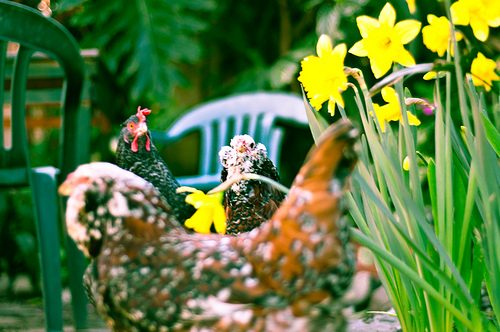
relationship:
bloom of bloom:
[447, 0, 499, 44] [447, 0, 498, 45]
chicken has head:
[108, 100, 194, 227] [123, 105, 148, 141]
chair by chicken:
[0, 0, 85, 330] [56, 97, 436, 332]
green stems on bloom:
[365, 128, 472, 329] [295, 32, 349, 116]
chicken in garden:
[108, 100, 194, 227] [1, 1, 477, 328]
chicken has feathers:
[97, 100, 199, 226] [153, 160, 166, 185]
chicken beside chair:
[108, 100, 194, 227] [0, 0, 85, 330]